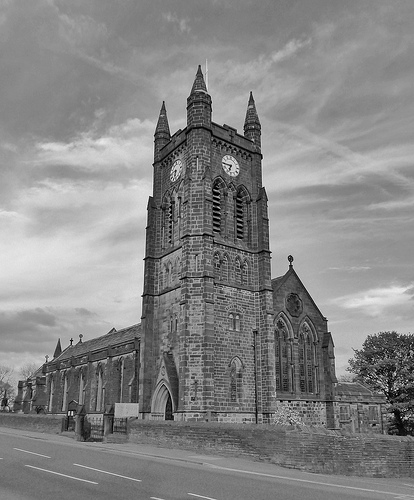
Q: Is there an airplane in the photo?
A: No, there are no airplanes.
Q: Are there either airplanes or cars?
A: No, there are no airplanes or cars.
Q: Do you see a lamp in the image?
A: No, there are no lamps.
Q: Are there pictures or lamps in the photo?
A: No, there are no lamps or pictures.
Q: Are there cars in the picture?
A: No, there are no cars.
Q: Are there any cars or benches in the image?
A: No, there are no cars or benches.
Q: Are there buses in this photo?
A: No, there are no buses.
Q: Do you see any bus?
A: No, there are no buses.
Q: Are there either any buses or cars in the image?
A: No, there are no buses or cars.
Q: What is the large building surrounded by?
A: The building is surrounded by the wall.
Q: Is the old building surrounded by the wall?
A: Yes, the building is surrounded by the wall.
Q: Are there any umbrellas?
A: No, there are no umbrellas.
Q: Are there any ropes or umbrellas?
A: No, there are no umbrellas or ropes.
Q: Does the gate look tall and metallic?
A: Yes, the gate is tall and metallic.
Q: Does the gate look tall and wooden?
A: No, the gate is tall but metallic.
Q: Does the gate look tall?
A: Yes, the gate is tall.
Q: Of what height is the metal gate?
A: The gate is tall.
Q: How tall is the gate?
A: The gate is tall.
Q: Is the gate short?
A: No, the gate is tall.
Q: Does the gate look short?
A: No, the gate is tall.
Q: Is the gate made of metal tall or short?
A: The gate is tall.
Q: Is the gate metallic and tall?
A: Yes, the gate is metallic and tall.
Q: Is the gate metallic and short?
A: No, the gate is metallic but tall.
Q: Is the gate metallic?
A: Yes, the gate is metallic.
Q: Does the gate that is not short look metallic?
A: Yes, the gate is metallic.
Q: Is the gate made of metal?
A: Yes, the gate is made of metal.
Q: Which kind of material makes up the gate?
A: The gate is made of metal.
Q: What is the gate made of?
A: The gate is made of metal.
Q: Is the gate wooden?
A: No, the gate is metallic.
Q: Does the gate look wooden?
A: No, the gate is metallic.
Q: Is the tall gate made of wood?
A: No, the gate is made of metal.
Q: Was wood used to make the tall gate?
A: No, the gate is made of metal.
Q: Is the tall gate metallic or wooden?
A: The gate is metallic.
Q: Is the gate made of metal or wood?
A: The gate is made of metal.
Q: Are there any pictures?
A: No, there are no pictures.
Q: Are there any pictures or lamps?
A: No, there are no pictures or lamps.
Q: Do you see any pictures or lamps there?
A: No, there are no pictures or lamps.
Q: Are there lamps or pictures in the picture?
A: No, there are no pictures or lamps.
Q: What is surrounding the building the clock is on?
A: The wall is surrounding the building.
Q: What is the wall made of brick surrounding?
A: The wall is surrounding the building.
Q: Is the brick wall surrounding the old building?
A: Yes, the wall is surrounding the building.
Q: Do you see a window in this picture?
A: Yes, there is a window.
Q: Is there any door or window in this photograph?
A: Yes, there is a window.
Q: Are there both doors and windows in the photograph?
A: Yes, there are both a window and a door.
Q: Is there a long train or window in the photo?
A: Yes, there is a long window.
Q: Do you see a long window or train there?
A: Yes, there is a long window.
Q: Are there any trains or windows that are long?
A: Yes, the window is long.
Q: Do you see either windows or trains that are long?
A: Yes, the window is long.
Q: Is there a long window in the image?
A: Yes, there is a long window.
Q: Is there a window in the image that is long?
A: Yes, there is a window that is long.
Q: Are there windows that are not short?
A: Yes, there is a long window.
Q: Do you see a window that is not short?
A: Yes, there is a long window.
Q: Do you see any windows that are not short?
A: Yes, there is a long window.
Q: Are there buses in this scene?
A: No, there are no buses.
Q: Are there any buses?
A: No, there are no buses.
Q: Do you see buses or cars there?
A: No, there are no buses or cars.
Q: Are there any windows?
A: Yes, there is a window.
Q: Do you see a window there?
A: Yes, there is a window.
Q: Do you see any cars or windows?
A: Yes, there is a window.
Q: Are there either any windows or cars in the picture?
A: Yes, there is a window.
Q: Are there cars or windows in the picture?
A: Yes, there is a window.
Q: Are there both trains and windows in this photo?
A: No, there is a window but no trains.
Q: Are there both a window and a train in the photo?
A: No, there is a window but no trains.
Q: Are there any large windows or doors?
A: Yes, there is a large window.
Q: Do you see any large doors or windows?
A: Yes, there is a large window.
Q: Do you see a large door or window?
A: Yes, there is a large window.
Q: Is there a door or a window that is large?
A: Yes, the window is large.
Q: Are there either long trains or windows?
A: Yes, there is a long window.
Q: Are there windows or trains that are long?
A: Yes, the window is long.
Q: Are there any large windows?
A: Yes, there is a large window.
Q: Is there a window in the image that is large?
A: Yes, there is a window that is large.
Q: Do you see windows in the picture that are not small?
A: Yes, there is a large window.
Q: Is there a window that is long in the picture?
A: Yes, there is a long window.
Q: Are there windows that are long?
A: Yes, there is a window that is long.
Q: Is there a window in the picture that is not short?
A: Yes, there is a long window.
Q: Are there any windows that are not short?
A: Yes, there is a long window.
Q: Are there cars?
A: No, there are no cars.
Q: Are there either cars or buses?
A: No, there are no cars or buses.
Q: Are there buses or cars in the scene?
A: No, there are no cars or buses.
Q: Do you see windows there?
A: Yes, there is a window.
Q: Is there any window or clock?
A: Yes, there is a window.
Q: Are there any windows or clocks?
A: Yes, there is a window.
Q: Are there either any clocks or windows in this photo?
A: Yes, there is a window.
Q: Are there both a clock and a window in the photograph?
A: Yes, there are both a window and a clock.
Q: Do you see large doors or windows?
A: Yes, there is a large window.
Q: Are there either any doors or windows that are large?
A: Yes, the window is large.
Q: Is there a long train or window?
A: Yes, there is a long window.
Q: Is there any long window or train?
A: Yes, there is a long window.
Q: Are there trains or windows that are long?
A: Yes, the window is long.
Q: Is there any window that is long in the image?
A: Yes, there is a long window.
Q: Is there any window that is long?
A: Yes, there is a window that is long.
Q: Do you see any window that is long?
A: Yes, there is a window that is long.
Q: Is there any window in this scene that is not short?
A: Yes, there is a long window.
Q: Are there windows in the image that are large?
A: Yes, there is a large window.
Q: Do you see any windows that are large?
A: Yes, there is a window that is large.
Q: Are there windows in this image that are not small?
A: Yes, there is a large window.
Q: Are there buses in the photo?
A: No, there are no buses.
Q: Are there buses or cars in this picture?
A: No, there are no buses or cars.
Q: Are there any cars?
A: No, there are no cars.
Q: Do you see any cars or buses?
A: No, there are no cars or buses.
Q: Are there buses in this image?
A: No, there are no buses.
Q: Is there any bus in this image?
A: No, there are no buses.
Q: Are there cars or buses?
A: No, there are no buses or cars.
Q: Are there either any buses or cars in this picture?
A: No, there are no buses or cars.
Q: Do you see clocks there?
A: Yes, there is a clock.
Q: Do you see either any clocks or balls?
A: Yes, there is a clock.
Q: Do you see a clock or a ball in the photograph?
A: Yes, there is a clock.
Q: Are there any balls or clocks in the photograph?
A: Yes, there is a clock.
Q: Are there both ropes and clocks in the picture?
A: No, there is a clock but no ropes.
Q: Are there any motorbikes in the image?
A: No, there are no motorbikes.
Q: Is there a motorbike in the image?
A: No, there are no motorcycles.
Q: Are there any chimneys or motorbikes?
A: No, there are no motorbikes or chimneys.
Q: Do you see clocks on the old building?
A: Yes, there is a clock on the building.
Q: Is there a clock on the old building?
A: Yes, there is a clock on the building.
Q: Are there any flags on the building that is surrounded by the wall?
A: No, there is a clock on the building.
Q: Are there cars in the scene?
A: No, there are no cars.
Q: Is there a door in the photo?
A: Yes, there is a door.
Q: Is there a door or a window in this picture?
A: Yes, there is a door.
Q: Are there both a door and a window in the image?
A: Yes, there are both a door and a window.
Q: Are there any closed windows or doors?
A: Yes, there is a closed door.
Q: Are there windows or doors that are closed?
A: Yes, the door is closed.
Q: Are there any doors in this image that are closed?
A: Yes, there is a door that is closed.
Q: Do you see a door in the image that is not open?
A: Yes, there is an closed door.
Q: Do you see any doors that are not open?
A: Yes, there is an closed door.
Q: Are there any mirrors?
A: No, there are no mirrors.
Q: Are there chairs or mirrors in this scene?
A: No, there are no mirrors or chairs.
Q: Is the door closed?
A: Yes, the door is closed.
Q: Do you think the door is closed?
A: Yes, the door is closed.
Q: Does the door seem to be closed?
A: Yes, the door is closed.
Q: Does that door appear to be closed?
A: Yes, the door is closed.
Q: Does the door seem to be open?
A: No, the door is closed.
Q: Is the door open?
A: No, the door is closed.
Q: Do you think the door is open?
A: No, the door is closed.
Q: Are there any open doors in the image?
A: No, there is a door but it is closed.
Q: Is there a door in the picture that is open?
A: No, there is a door but it is closed.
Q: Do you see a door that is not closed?
A: No, there is a door but it is closed.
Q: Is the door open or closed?
A: The door is closed.